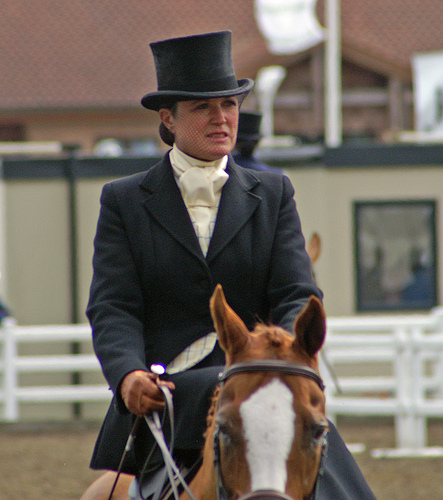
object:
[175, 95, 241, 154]
person's face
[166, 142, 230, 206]
tie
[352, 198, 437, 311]
picture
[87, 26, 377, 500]
lady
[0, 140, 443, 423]
building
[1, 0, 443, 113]
roof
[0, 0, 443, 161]
building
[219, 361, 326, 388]
dark straps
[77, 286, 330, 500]
horse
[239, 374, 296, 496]
marking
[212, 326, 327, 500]
face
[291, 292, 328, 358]
ear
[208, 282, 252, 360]
ear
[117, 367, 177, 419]
glove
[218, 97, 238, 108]
eye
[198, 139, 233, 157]
chin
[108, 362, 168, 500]
riding whip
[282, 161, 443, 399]
wall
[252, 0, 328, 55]
flag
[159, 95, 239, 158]
head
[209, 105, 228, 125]
nose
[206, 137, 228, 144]
lips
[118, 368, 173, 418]
hand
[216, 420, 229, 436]
eye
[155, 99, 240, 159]
netting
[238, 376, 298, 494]
coloring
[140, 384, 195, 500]
reigns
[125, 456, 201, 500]
saddle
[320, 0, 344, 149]
pole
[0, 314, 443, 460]
fence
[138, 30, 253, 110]
hat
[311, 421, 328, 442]
eye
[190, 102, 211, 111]
eye